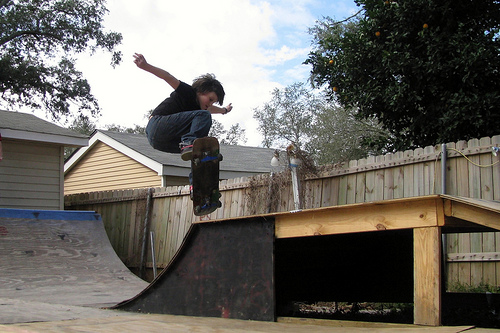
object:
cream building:
[0, 109, 90, 212]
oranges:
[423, 23, 428, 29]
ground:
[279, 301, 499, 333]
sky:
[0, 0, 368, 146]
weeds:
[446, 281, 499, 294]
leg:
[412, 227, 439, 325]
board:
[193, 137, 224, 215]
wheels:
[194, 158, 201, 167]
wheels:
[195, 205, 200, 213]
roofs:
[62, 129, 279, 176]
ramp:
[104, 215, 275, 321]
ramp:
[0, 206, 152, 307]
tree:
[0, 0, 125, 124]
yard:
[2, 0, 500, 333]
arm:
[208, 105, 227, 114]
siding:
[63, 180, 161, 195]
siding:
[0, 197, 60, 207]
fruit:
[375, 31, 381, 37]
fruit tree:
[302, 0, 500, 153]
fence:
[63, 134, 499, 294]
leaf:
[325, 96, 333, 103]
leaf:
[363, 115, 368, 119]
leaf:
[376, 116, 383, 123]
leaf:
[400, 134, 406, 141]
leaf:
[393, 49, 398, 55]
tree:
[62, 112, 99, 162]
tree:
[221, 122, 248, 145]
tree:
[254, 82, 327, 151]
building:
[62, 127, 287, 193]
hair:
[191, 73, 225, 105]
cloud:
[85, 0, 276, 121]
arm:
[144, 65, 183, 89]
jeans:
[145, 110, 212, 185]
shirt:
[148, 80, 201, 117]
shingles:
[57, 142, 162, 196]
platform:
[104, 193, 500, 326]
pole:
[441, 143, 446, 193]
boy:
[130, 52, 232, 198]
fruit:
[329, 60, 334, 64]